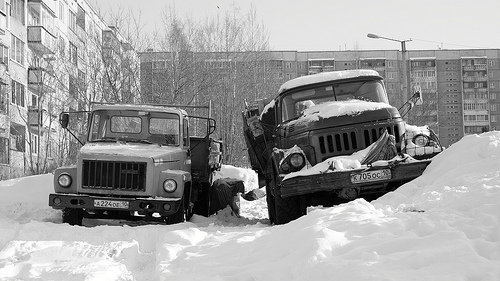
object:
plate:
[93, 200, 130, 210]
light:
[290, 154, 304, 167]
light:
[367, 33, 409, 124]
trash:
[359, 128, 398, 170]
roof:
[273, 74, 384, 96]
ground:
[306, 164, 359, 214]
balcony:
[28, 25, 57, 55]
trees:
[1, 0, 317, 175]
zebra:
[95, 5, 271, 92]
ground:
[346, 132, 398, 182]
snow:
[0, 68, 499, 280]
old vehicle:
[241, 69, 446, 225]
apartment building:
[1, 0, 140, 180]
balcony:
[30, 64, 58, 94]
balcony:
[30, 109, 56, 134]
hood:
[274, 106, 400, 137]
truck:
[49, 100, 246, 228]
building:
[140, 49, 499, 169]